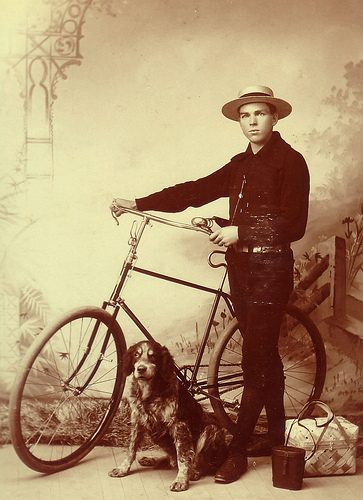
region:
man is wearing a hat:
[222, 85, 279, 156]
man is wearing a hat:
[213, 72, 292, 149]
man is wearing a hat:
[224, 71, 289, 159]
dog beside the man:
[113, 72, 307, 498]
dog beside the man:
[114, 72, 304, 465]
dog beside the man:
[113, 63, 318, 490]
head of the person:
[219, 61, 311, 143]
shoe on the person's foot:
[205, 444, 256, 496]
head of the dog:
[116, 327, 179, 386]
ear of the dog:
[153, 331, 184, 381]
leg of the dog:
[158, 415, 207, 493]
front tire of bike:
[0, 303, 138, 469]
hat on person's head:
[210, 83, 301, 118]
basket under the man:
[275, 394, 357, 473]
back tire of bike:
[186, 302, 347, 432]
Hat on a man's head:
[214, 77, 297, 146]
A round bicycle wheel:
[2, 300, 129, 478]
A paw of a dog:
[101, 450, 132, 477]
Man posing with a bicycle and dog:
[1, 76, 330, 494]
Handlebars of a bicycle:
[103, 190, 219, 245]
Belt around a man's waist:
[215, 232, 290, 259]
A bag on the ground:
[278, 393, 356, 477]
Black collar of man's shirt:
[226, 125, 291, 174]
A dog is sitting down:
[103, 333, 233, 494]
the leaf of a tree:
[80, 414, 89, 419]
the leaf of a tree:
[114, 425, 121, 436]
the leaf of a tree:
[84, 421, 93, 426]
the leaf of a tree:
[115, 424, 124, 429]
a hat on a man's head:
[213, 76, 298, 107]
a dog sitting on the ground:
[95, 327, 215, 496]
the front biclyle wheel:
[0, 302, 142, 485]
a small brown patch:
[265, 441, 309, 497]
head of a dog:
[108, 321, 196, 402]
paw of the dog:
[91, 451, 137, 491]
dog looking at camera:
[103, 320, 187, 400]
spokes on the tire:
[0, 311, 130, 451]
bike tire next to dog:
[1, 306, 138, 450]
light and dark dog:
[66, 323, 246, 469]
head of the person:
[213, 80, 308, 146]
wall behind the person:
[70, 20, 198, 110]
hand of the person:
[195, 210, 247, 266]